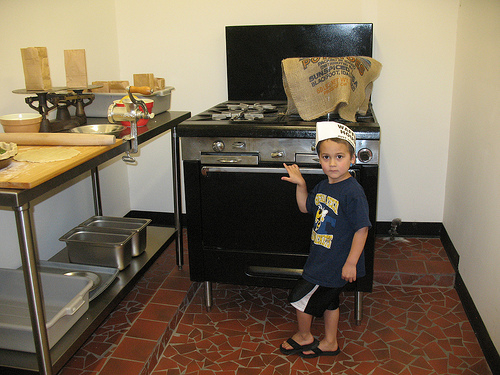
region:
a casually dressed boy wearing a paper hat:
[278, 118, 377, 358]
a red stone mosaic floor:
[41, 226, 493, 373]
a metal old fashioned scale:
[16, 83, 108, 135]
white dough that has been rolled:
[15, 145, 85, 165]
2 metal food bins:
[58, 210, 158, 273]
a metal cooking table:
[2, 96, 192, 372]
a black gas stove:
[175, 19, 390, 329]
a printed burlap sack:
[282, 49, 382, 126]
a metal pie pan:
[66, 120, 134, 135]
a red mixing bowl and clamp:
[104, 84, 161, 165]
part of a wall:
[466, 165, 478, 181]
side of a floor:
[415, 352, 420, 356]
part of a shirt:
[326, 264, 335, 279]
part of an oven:
[228, 220, 234, 243]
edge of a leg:
[301, 308, 306, 327]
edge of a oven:
[204, 222, 211, 229]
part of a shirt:
[326, 249, 328, 251]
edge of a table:
[51, 208, 68, 225]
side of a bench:
[117, 268, 120, 277]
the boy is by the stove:
[261, 110, 429, 372]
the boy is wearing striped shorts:
[285, 173, 380, 327]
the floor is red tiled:
[197, 310, 220, 361]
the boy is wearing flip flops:
[273, 294, 318, 352]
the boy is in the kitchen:
[157, 102, 453, 359]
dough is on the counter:
[10, 123, 69, 197]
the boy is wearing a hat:
[304, 102, 377, 140]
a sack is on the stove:
[267, 38, 468, 141]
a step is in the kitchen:
[104, 285, 206, 344]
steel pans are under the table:
[49, 225, 201, 284]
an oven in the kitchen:
[192, 24, 280, 239]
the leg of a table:
[11, 210, 69, 370]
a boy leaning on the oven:
[291, 123, 378, 343]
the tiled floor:
[189, 318, 275, 373]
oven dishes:
[66, 209, 157, 276]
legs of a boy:
[289, 308, 375, 365]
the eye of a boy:
[324, 152, 329, 157]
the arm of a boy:
[275, 165, 305, 215]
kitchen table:
[0, 96, 180, 366]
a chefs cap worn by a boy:
[311, 120, 356, 145]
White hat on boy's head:
[309, 116, 361, 180]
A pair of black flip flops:
[276, 328, 344, 363]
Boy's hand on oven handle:
[275, 117, 375, 217]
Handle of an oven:
[197, 160, 359, 183]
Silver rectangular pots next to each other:
[61, 210, 154, 272]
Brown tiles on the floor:
[60, 234, 494, 374]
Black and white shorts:
[284, 275, 344, 320]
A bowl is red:
[113, 94, 157, 129]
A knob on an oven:
[206, 136, 227, 157]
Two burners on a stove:
[197, 97, 285, 125]